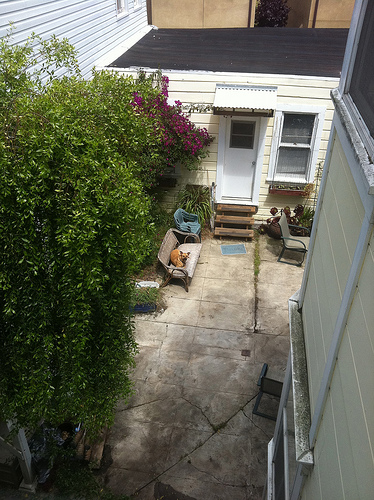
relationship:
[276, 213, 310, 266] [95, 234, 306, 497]
chair on concrete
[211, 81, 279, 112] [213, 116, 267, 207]
awning over door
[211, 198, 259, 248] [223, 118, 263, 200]
steps below door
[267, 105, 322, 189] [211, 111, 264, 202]
window next door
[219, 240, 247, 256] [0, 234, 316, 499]
door on floor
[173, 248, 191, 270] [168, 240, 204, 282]
dog lying on seat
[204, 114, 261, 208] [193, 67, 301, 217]
door on house